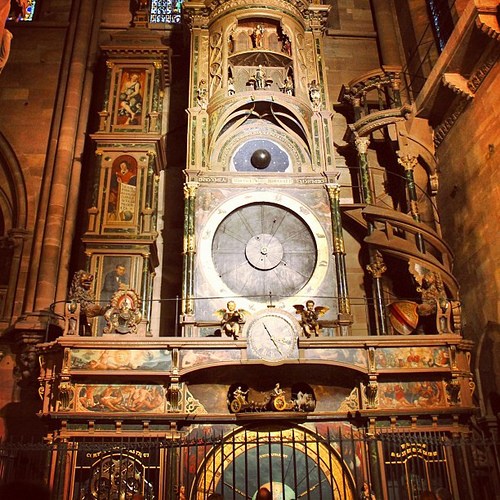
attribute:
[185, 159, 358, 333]
clock — black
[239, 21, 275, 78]
statue — tiny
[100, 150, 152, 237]
painting — older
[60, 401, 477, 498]
gate — black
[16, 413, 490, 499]
gate — metal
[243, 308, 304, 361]
clock — small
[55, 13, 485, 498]
tower — beautiful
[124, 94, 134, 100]
dress — green